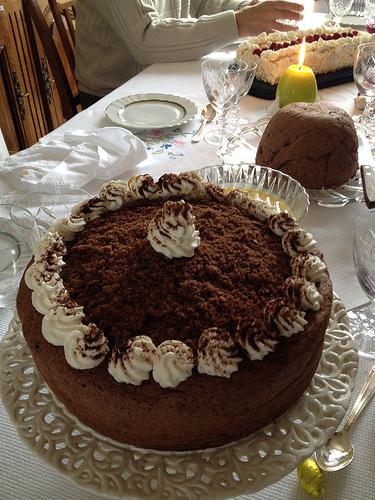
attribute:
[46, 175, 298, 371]
crumbles — brown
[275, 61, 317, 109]
candle — bright green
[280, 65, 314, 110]
candle — burning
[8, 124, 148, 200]
napkin — linen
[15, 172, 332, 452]
chokolate cake — chocolate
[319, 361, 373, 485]
spoon — silver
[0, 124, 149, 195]
napkin — crumpled up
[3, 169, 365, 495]
plate — decorative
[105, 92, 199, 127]
plate — white, empty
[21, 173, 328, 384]
icing — decorative, white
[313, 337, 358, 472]
spoon — silver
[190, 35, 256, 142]
glass — empty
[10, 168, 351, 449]
dessert — chocolate, round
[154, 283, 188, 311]
crumbles — brown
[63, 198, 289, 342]
crumbles — brown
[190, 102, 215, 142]
spoon — silver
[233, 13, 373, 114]
cake — rectangular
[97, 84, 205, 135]
plate — serving, white, round, small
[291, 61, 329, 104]
candle — lit, lime green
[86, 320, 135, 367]
crumbles — brown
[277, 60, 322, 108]
candle — yellow